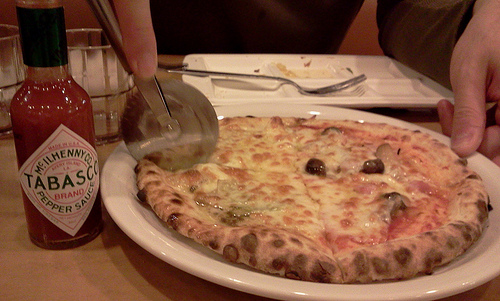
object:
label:
[15, 123, 100, 236]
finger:
[110, 0, 158, 82]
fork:
[158, 63, 367, 96]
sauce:
[10, 1, 105, 251]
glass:
[66, 27, 140, 145]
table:
[0, 121, 499, 300]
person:
[114, 1, 499, 165]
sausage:
[303, 157, 328, 180]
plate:
[100, 102, 499, 300]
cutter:
[85, 0, 219, 172]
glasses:
[0, 24, 29, 137]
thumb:
[448, 51, 489, 158]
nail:
[449, 130, 473, 148]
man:
[114, 0, 499, 167]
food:
[134, 114, 494, 283]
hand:
[437, 0, 500, 168]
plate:
[183, 53, 454, 106]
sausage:
[360, 158, 386, 175]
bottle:
[9, 0, 104, 251]